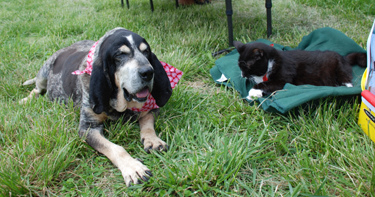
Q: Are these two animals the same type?
A: No, they are dogs and cats.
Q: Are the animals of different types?
A: Yes, they are dogs and cats.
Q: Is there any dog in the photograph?
A: Yes, there is a dog.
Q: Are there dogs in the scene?
A: Yes, there is a dog.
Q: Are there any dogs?
A: Yes, there is a dog.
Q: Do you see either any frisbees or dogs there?
A: Yes, there is a dog.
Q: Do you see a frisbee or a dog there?
A: Yes, there is a dog.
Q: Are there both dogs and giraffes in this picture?
A: No, there is a dog but no giraffes.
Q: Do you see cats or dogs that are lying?
A: Yes, the dog is lying.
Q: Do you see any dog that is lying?
A: Yes, there is a dog that is lying.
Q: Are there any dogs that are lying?
A: Yes, there is a dog that is lying.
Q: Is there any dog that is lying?
A: Yes, there is a dog that is lying.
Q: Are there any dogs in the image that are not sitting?
A: Yes, there is a dog that is lying.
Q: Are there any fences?
A: No, there are no fences.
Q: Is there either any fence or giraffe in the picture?
A: No, there are no fences or giraffes.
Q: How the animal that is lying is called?
A: The animal is a dog.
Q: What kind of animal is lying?
A: The animal is a dog.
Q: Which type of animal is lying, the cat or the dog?
A: The dog is lying.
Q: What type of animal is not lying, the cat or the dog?
A: The cat is not lying.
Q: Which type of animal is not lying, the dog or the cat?
A: The cat is not lying.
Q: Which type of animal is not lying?
A: The animal is a cat.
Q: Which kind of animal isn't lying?
A: The animal is a cat.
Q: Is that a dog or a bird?
A: That is a dog.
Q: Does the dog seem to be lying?
A: Yes, the dog is lying.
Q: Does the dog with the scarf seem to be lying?
A: Yes, the dog is lying.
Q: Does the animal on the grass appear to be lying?
A: Yes, the dog is lying.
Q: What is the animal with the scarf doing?
A: The dog is lying.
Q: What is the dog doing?
A: The dog is lying.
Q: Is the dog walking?
A: No, the dog is lying.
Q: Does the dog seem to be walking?
A: No, the dog is lying.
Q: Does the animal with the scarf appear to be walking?
A: No, the dog is lying.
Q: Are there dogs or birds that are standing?
A: No, there is a dog but it is lying.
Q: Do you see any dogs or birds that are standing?
A: No, there is a dog but it is lying.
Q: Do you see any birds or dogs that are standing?
A: No, there is a dog but it is lying.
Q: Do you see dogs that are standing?
A: No, there is a dog but it is lying.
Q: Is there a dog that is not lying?
A: No, there is a dog but it is lying.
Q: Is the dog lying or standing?
A: The dog is lying.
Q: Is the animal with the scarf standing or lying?
A: The dog is lying.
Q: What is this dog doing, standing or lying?
A: The dog is lying.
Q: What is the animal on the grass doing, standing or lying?
A: The dog is lying.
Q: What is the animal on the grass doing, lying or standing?
A: The dog is lying.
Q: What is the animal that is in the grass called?
A: The animal is a dog.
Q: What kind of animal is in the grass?
A: The animal is a dog.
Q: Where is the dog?
A: The dog is in the grass.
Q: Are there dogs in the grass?
A: Yes, there is a dog in the grass.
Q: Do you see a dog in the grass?
A: Yes, there is a dog in the grass.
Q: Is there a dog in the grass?
A: Yes, there is a dog in the grass.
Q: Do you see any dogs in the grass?
A: Yes, there is a dog in the grass.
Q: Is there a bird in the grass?
A: No, there is a dog in the grass.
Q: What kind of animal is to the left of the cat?
A: The animal is a dog.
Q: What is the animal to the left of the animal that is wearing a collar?
A: The animal is a dog.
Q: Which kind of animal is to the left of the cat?
A: The animal is a dog.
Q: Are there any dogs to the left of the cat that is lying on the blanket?
A: Yes, there is a dog to the left of the cat.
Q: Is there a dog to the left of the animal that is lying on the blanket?
A: Yes, there is a dog to the left of the cat.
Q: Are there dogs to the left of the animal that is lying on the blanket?
A: Yes, there is a dog to the left of the cat.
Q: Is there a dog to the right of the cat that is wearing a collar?
A: No, the dog is to the left of the cat.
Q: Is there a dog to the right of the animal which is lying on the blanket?
A: No, the dog is to the left of the cat.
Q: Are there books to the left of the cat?
A: No, there is a dog to the left of the cat.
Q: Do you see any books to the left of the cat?
A: No, there is a dog to the left of the cat.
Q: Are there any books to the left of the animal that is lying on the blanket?
A: No, there is a dog to the left of the cat.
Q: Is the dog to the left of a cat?
A: Yes, the dog is to the left of a cat.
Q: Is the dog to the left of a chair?
A: No, the dog is to the left of a cat.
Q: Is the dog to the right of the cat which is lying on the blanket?
A: No, the dog is to the left of the cat.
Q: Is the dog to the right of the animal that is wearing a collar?
A: No, the dog is to the left of the cat.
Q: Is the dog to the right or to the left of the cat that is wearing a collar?
A: The dog is to the left of the cat.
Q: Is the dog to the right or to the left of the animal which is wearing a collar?
A: The dog is to the left of the cat.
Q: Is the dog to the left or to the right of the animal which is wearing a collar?
A: The dog is to the left of the cat.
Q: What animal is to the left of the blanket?
A: The animal is a dog.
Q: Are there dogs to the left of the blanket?
A: Yes, there is a dog to the left of the blanket.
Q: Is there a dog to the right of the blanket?
A: No, the dog is to the left of the blanket.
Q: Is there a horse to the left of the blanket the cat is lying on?
A: No, there is a dog to the left of the blanket.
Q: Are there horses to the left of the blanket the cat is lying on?
A: No, there is a dog to the left of the blanket.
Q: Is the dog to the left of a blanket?
A: Yes, the dog is to the left of a blanket.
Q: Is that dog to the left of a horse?
A: No, the dog is to the left of a blanket.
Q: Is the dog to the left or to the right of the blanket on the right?
A: The dog is to the left of the blanket.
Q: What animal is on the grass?
A: The dog is on the grass.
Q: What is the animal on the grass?
A: The animal is a dog.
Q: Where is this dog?
A: The dog is on the grass.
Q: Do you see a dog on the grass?
A: Yes, there is a dog on the grass.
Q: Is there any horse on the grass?
A: No, there is a dog on the grass.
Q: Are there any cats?
A: Yes, there is a cat.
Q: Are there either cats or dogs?
A: Yes, there is a cat.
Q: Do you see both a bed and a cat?
A: No, there is a cat but no beds.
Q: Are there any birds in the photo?
A: No, there are no birds.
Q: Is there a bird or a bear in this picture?
A: No, there are no birds or bears.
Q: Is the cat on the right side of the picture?
A: Yes, the cat is on the right of the image.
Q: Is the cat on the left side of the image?
A: No, the cat is on the right of the image.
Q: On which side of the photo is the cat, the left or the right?
A: The cat is on the right of the image.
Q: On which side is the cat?
A: The cat is on the right of the image.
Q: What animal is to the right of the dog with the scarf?
A: The animal is a cat.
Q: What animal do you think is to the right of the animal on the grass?
A: The animal is a cat.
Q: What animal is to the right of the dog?
A: The animal is a cat.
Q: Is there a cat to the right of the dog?
A: Yes, there is a cat to the right of the dog.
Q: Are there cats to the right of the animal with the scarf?
A: Yes, there is a cat to the right of the dog.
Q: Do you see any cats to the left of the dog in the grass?
A: No, the cat is to the right of the dog.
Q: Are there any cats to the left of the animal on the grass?
A: No, the cat is to the right of the dog.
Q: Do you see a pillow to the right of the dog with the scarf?
A: No, there is a cat to the right of the dog.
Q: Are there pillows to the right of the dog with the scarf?
A: No, there is a cat to the right of the dog.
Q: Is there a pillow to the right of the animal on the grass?
A: No, there is a cat to the right of the dog.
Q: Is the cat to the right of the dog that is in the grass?
A: Yes, the cat is to the right of the dog.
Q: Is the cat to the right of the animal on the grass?
A: Yes, the cat is to the right of the dog.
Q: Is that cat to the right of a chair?
A: No, the cat is to the right of the dog.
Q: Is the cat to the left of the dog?
A: No, the cat is to the right of the dog.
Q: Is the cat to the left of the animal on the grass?
A: No, the cat is to the right of the dog.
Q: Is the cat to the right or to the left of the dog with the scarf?
A: The cat is to the right of the dog.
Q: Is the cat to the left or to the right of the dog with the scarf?
A: The cat is to the right of the dog.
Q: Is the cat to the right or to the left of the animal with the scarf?
A: The cat is to the right of the dog.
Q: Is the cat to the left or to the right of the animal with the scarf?
A: The cat is to the right of the dog.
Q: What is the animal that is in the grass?
A: The animal is a cat.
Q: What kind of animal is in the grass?
A: The animal is a cat.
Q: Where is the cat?
A: The cat is in the grass.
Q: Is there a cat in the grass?
A: Yes, there is a cat in the grass.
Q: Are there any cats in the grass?
A: Yes, there is a cat in the grass.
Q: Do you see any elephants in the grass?
A: No, there is a cat in the grass.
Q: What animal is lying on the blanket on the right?
A: The cat is lying on the blanket.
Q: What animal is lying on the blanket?
A: The cat is lying on the blanket.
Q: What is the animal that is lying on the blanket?
A: The animal is a cat.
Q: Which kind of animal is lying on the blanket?
A: The animal is a cat.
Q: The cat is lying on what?
A: The cat is lying on the blanket.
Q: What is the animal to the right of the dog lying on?
A: The cat is lying on the blanket.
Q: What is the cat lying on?
A: The cat is lying on the blanket.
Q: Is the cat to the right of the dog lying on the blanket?
A: Yes, the cat is lying on the blanket.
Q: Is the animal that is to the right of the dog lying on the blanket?
A: Yes, the cat is lying on the blanket.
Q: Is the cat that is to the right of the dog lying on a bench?
A: No, the cat is lying on the blanket.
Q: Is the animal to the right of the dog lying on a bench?
A: No, the cat is lying on the blanket.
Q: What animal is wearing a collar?
A: The cat is wearing a collar.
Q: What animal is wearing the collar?
A: The cat is wearing a collar.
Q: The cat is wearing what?
A: The cat is wearing a collar.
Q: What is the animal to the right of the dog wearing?
A: The cat is wearing a collar.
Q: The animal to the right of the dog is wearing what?
A: The cat is wearing a collar.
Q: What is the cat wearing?
A: The cat is wearing a collar.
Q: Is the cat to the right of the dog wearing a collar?
A: Yes, the cat is wearing a collar.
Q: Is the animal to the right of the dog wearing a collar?
A: Yes, the cat is wearing a collar.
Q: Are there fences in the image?
A: No, there are no fences.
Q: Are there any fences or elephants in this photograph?
A: No, there are no fences or elephants.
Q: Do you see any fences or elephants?
A: No, there are no fences or elephants.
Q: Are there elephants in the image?
A: No, there are no elephants.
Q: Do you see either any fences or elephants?
A: No, there are no elephants or fences.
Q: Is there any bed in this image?
A: No, there are no beds.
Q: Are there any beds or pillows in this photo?
A: No, there are no beds or pillows.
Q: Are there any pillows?
A: No, there are no pillows.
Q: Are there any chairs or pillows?
A: No, there are no pillows or chairs.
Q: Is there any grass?
A: Yes, there is grass.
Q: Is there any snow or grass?
A: Yes, there is grass.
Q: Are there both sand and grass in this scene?
A: No, there is grass but no sand.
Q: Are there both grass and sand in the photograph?
A: No, there is grass but no sand.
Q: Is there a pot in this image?
A: No, there are no pots.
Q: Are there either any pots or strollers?
A: No, there are no pots or strollers.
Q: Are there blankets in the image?
A: Yes, there is a blanket.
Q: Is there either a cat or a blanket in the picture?
A: Yes, there is a blanket.